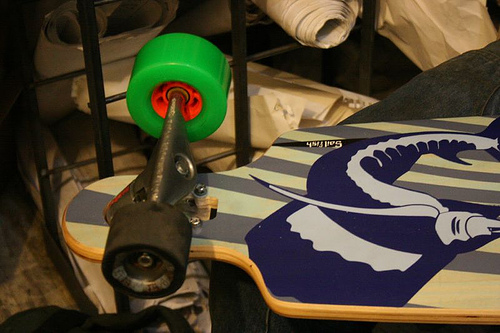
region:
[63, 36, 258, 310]
wheels on a long board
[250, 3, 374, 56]
a scroll of paper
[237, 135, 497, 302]
decal on the board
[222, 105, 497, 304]
the decal is blue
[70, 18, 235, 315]
a skateboard with a green wheel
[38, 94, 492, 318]
a skateboard upside down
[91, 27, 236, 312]
a skateboard with a black wheel and a green wheel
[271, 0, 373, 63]
a roll of paper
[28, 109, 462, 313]
a wooden skateboard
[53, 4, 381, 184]
a black iron shelf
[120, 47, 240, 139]
a green wheel with red inside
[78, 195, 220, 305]
a black wheel on a skatboard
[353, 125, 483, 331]
a blue and white picture on a skateboard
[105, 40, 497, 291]
a skateboard on someones lap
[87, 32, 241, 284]
the wheels are green and black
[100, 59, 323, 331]
the wheels are green and black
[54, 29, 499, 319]
an upside down skateboard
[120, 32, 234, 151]
a green and red skateboard wheel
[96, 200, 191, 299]
a black skateboard wheel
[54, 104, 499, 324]
a blue and white skateboard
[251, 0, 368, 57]
a roll of white paper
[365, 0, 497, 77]
crumpled white paper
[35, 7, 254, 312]
black metal framing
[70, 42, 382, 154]
rolled up white papers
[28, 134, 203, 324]
rolled up white papers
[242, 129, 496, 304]
a blue and white graphic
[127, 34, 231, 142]
green long board wheel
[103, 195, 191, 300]
black long board wheel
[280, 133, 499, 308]
blue and white graphic on a long board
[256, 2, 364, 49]
end of a rolled up piece of paper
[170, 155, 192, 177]
long board king pin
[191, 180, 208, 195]
head of a small screw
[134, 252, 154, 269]
bolt and nut holding a wheel on to trucks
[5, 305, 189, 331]
subsection of a green bag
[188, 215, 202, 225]
head of a small screw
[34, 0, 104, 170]
roll of paper held by metal fram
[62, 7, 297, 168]
a green skateboard wheel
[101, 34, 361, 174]
a green and orange wheel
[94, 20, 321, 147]
green and orange wheel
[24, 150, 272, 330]
a black skateboard wheel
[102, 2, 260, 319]
two different skateboard wheels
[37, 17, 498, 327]
a skateboard turned upside down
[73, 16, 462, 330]
skateboard with two different wheels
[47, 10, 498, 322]
skateboard with a green wheel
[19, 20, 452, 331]
a skateboard with a black wheel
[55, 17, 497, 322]
a skateboard inside